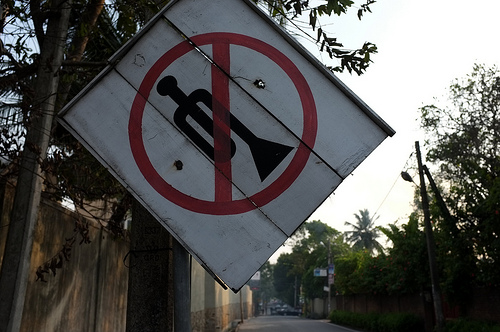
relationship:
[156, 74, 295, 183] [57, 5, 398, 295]
black trumpet printed on sign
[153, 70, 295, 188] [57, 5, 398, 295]
black trumpet on sign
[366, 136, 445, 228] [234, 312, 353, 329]
electric wire on street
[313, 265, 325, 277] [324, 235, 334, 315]
signs on pole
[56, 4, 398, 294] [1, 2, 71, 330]
signs on pole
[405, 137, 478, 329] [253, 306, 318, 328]
street light on road